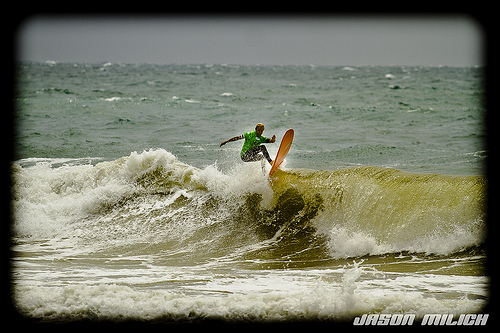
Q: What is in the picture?
A: Surfer.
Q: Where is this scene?
A: The waves.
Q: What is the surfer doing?
A: Riding the waves.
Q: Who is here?
A: The rider.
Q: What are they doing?
A: Surfing.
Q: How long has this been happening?
A: Since the wave rose.